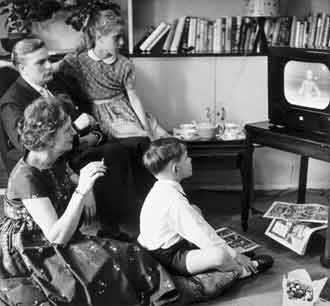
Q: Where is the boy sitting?
A: The floor.